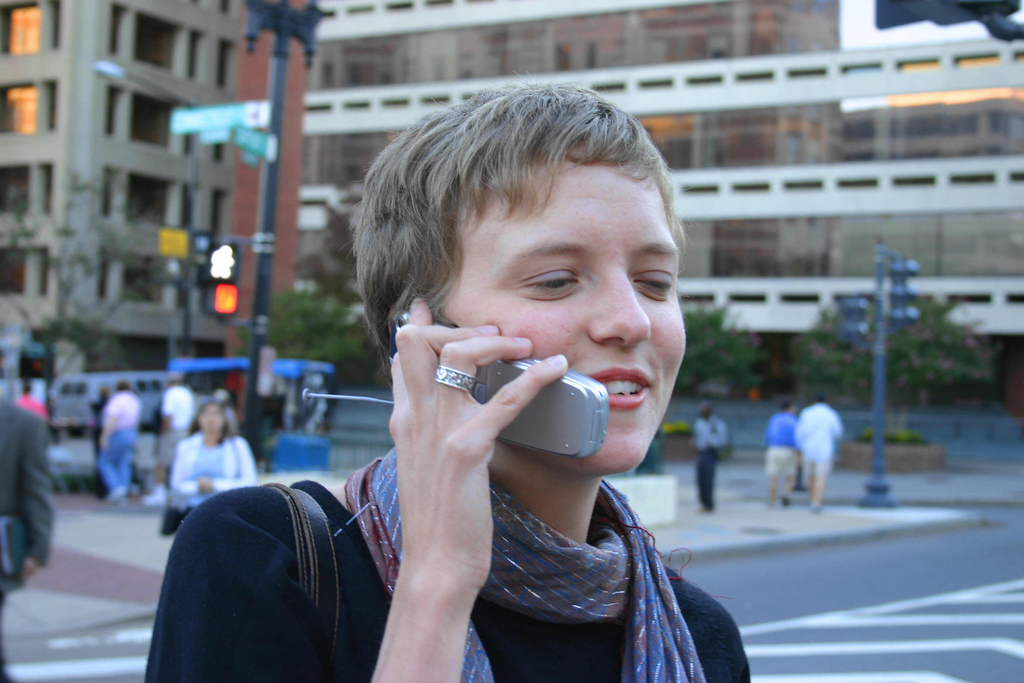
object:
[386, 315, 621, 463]
cell phone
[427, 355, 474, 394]
ring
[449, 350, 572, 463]
finger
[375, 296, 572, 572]
hand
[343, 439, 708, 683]
scarf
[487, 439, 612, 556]
neck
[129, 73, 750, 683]
lady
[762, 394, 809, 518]
person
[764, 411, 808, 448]
shirt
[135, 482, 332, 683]
sleeves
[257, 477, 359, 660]
strap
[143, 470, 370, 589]
shoulder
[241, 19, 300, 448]
light pole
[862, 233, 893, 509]
pole.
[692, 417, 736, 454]
shirt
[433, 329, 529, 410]
finger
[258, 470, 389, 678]
bag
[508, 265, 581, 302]
eye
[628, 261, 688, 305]
eye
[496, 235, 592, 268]
eyebrow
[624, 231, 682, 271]
eyebrown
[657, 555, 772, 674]
shoulder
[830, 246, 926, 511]
lamp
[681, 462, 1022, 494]
sidewalk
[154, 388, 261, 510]
woman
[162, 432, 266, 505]
cardigan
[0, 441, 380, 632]
sidewalk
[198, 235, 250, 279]
sign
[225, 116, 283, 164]
sign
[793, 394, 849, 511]
person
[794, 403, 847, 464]
shirt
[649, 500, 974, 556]
sidewalk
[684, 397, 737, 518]
man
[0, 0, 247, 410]
building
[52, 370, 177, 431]
bus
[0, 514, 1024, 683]
road